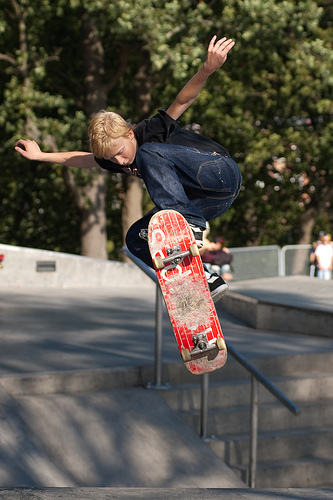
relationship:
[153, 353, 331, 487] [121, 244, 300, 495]
steps next to rail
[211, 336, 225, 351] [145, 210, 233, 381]
wheels of skateboard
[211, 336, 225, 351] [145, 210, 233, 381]
wheels on skateboard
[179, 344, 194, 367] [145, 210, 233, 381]
wheels on skateboard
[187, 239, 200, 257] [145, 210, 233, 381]
wheels on skateboard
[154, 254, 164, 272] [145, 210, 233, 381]
wheels on skateboard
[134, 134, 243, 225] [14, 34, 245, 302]
jeans on boy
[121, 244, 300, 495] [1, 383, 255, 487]
rail near ramp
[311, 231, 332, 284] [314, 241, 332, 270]
person in shirt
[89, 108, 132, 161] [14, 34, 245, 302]
hair on boy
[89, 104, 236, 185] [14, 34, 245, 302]
t-shirt on boy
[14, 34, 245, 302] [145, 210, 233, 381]
boy on skateboard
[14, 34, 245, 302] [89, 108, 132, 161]
boy has hair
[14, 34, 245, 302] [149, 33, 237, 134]
boy extended arms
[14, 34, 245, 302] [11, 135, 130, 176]
boy extended arms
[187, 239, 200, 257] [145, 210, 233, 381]
wheels of skateboard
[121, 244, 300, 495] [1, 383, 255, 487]
rail on side of ramp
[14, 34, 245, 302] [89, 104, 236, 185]
boy has t-shirt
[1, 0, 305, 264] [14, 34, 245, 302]
trees behind boy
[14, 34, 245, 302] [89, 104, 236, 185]
boy wearing t-shirt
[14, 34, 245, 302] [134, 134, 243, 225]
boy wearing jeans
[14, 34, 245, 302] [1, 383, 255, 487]
boy jumping over ramp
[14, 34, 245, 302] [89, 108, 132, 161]
boy with hair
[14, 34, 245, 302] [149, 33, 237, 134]
boy outstretched arms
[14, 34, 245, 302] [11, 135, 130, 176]
boy outstretched arms